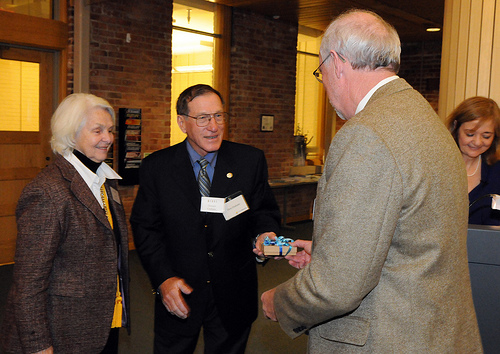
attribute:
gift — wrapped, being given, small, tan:
[260, 235, 299, 259]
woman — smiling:
[5, 92, 132, 354]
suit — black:
[128, 138, 283, 353]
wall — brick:
[69, 0, 384, 251]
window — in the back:
[170, 1, 229, 147]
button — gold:
[223, 171, 234, 179]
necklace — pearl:
[461, 151, 483, 178]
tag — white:
[488, 192, 499, 209]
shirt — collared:
[465, 157, 498, 225]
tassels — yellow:
[100, 185, 123, 329]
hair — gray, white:
[47, 91, 119, 159]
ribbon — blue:
[263, 233, 294, 257]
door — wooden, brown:
[0, 45, 57, 268]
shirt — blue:
[184, 142, 219, 196]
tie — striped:
[195, 156, 213, 198]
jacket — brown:
[0, 152, 133, 353]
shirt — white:
[54, 146, 124, 209]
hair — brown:
[446, 95, 499, 165]